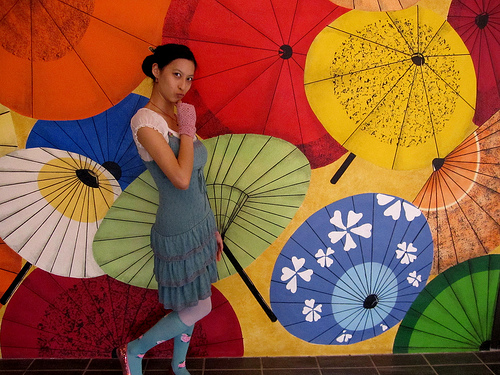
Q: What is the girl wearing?
A: Dress.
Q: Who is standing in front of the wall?
A: Girl in a dress.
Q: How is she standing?
A: On one leg.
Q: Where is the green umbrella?
A: Lower right corner.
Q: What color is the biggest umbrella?
A: Red.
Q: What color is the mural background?
A: Yellow.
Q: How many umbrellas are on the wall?
A: 14.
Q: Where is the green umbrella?
A: Behind the girl.